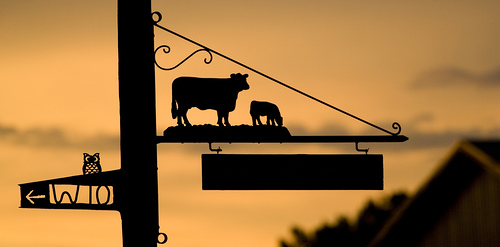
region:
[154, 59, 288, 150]
metal cows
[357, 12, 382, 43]
white clouds in blue sky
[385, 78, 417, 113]
white clouds in blue sky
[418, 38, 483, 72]
white clouds in blue sky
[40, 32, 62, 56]
white clouds in blue sky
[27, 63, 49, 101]
white clouds in blue sky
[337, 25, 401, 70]
white clouds in blue sky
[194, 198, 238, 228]
white clouds in blue sky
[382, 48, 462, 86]
white clouds in blue sky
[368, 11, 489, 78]
white clouds in blue sky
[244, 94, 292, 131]
metal cow on a sign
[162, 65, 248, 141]
large cow standing on metal sign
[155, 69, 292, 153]
two cows on metal sign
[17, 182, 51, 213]
arrow on a metal sign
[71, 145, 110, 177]
owl sitting as part of a metal sign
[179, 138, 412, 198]
a plate hanging bleow a metal sign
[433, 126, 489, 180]
a peak of a roof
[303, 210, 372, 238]
green trees beyond a building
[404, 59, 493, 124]
clouds in the sky at sunset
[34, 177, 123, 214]
the word OWL backwards on metal sign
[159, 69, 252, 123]
cow design on rail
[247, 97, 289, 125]
cow design on rail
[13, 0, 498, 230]
yellow sky in the background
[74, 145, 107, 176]
small owl design on pole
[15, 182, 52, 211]
arrow cut into pole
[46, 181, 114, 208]
w10 cut into pole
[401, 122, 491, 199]
rooftop on right of trees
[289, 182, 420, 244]
outline of trees by roof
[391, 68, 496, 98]
gray clouds in yellow sky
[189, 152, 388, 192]
dangling sign under cows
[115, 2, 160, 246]
Post with signs on it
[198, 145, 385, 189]
Sign hanging from metal bar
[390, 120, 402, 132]
Curled end of metal brace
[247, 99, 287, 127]
Calf shape on sign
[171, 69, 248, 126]
Cow shape on a sign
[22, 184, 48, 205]
Arrow on a metal sign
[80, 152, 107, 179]
Owl shape on a sign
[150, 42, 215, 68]
Curved bracket on a sign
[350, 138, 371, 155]
Metal hook for a sign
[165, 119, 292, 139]
Ground shape on a sign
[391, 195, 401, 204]
edge of a roof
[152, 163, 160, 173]
edge of a pole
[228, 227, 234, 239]
part of a shadow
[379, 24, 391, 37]
part of a cloud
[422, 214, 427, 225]
edge of a roof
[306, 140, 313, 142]
edge of a rail